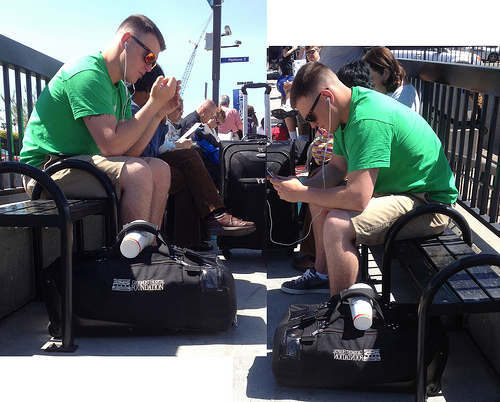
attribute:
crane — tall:
[173, 10, 212, 115]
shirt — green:
[322, 86, 463, 203]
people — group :
[20, 11, 461, 296]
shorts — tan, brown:
[345, 193, 455, 246]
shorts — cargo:
[348, 185, 455, 247]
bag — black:
[44, 199, 250, 358]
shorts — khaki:
[340, 192, 452, 245]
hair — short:
[124, 10, 160, 35]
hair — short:
[290, 57, 320, 90]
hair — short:
[371, 44, 405, 86]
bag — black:
[46, 235, 240, 337]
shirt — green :
[20, 50, 138, 167]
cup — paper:
[118, 219, 155, 258]